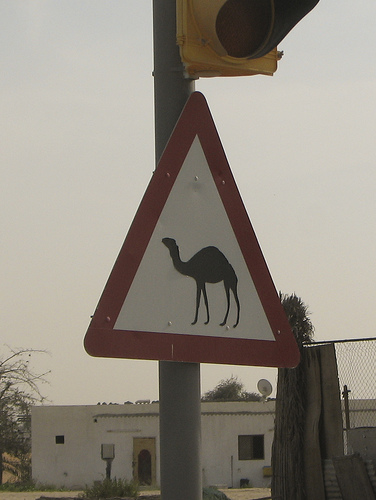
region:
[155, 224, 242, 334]
camel on the sign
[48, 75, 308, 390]
triangle shape sign on pole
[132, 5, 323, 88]
part of the street light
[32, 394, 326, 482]
white building in the background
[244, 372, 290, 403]
satalite on the roof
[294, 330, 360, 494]
wood against the fence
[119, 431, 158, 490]
yellow door with an arch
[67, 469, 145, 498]
bushes in front of the building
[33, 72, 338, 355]
red triangle shaped sign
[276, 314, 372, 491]
metal fence beside the sign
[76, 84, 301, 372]
Triangle shape for crossing sign.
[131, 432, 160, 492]
Closed yellow door with window.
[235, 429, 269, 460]
Dark window with curtain.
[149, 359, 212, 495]
Gray steel metal pole for sign.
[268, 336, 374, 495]
Pieces of unshaped wood for fence.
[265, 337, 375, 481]
Steel chain link metal fence.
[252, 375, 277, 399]
Round satellite dish for cable.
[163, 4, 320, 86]
Yellow metal casing on traffic light.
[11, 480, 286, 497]
Road made of beige sand.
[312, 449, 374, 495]
Gray corrugated sheet tin metal.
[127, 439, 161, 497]
Tan door on building.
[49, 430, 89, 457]
Black square on side of building.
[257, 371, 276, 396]
White antenna on top of building.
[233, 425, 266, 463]
Square opening in side of building.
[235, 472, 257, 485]
Small dark animal near building.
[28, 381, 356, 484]
Large white building in distance.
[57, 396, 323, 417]
Building has flat top.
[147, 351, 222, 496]
Gray pole attached to sign.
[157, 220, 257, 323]
Black camel on sign.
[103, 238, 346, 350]
Red and white sign shaped like triangle.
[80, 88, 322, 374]
a red white and black sign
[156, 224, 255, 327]
a camel on a sign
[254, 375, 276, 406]
satelite dish on building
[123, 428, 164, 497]
a yellow door on building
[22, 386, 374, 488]
a long white building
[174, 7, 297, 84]
part of a yellow traffic signal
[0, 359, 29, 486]
a tree beside the building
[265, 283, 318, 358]
part of a tree seen above the building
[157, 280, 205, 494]
a metal pole holding sign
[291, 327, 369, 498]
a chain link fence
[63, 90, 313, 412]
a triangle street sign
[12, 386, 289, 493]
a square white building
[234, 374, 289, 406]
satellite on the roof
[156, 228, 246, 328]
a black camel sign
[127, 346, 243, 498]
a gray metal pole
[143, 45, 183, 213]
a gray metal pole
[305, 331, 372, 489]
the fence has wires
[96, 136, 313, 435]
a triangle red and white sign